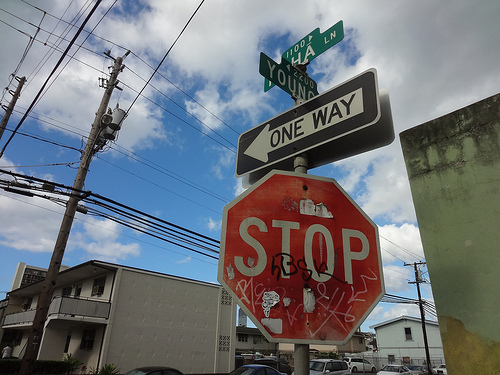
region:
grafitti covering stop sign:
[206, 158, 393, 349]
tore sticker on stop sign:
[291, 196, 338, 226]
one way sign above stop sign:
[218, 68, 390, 179]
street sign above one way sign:
[252, 49, 329, 111]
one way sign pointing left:
[221, 63, 388, 177]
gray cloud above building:
[351, 1, 498, 137]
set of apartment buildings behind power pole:
[1, 258, 245, 373]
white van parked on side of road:
[288, 347, 356, 374]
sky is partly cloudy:
[1, 1, 498, 331]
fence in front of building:
[338, 344, 441, 371]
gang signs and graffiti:
[233, 250, 380, 339]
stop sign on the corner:
[215, 167, 388, 349]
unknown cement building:
[396, 92, 498, 373]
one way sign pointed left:
[234, 69, 381, 179]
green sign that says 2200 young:
[257, 49, 328, 101]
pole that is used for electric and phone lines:
[17, 48, 132, 373]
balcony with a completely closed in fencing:
[46, 295, 113, 322]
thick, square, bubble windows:
[215, 332, 232, 353]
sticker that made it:
[257, 288, 282, 321]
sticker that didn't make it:
[296, 195, 335, 221]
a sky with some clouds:
[1, 1, 494, 234]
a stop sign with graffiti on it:
[206, 160, 396, 362]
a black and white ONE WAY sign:
[228, 61, 388, 177]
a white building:
[5, 256, 243, 371]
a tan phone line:
[25, 47, 138, 372]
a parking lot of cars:
[216, 335, 461, 371]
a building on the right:
[390, 81, 495, 367]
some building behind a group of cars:
[225, 311, 450, 358]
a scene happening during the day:
[11, 22, 492, 372]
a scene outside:
[20, 25, 495, 372]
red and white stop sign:
[194, 169, 392, 355]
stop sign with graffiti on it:
[193, 172, 415, 363]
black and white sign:
[226, 78, 418, 161]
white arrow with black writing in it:
[230, 83, 382, 169]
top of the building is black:
[394, 112, 494, 168]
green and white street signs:
[239, 20, 358, 101]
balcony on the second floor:
[2, 294, 124, 332]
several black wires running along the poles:
[79, 187, 215, 268]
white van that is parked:
[337, 351, 374, 373]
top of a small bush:
[91, 362, 123, 374]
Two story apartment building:
[2, 241, 270, 372]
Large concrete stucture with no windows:
[378, 100, 497, 372]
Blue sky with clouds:
[6, 3, 497, 303]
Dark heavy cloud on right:
[331, 4, 498, 129]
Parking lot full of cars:
[233, 335, 465, 372]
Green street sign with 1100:
[237, 21, 374, 77]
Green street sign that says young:
[248, 60, 353, 111]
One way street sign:
[204, 72, 406, 174]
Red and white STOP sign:
[208, 150, 401, 372]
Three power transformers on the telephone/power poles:
[78, 83, 143, 163]